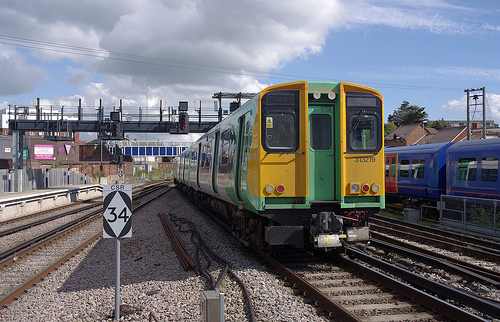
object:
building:
[108, 140, 193, 156]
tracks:
[0, 177, 500, 322]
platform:
[156, 174, 221, 276]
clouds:
[0, 1, 500, 123]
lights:
[349, 183, 381, 194]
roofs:
[384, 124, 482, 146]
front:
[259, 81, 384, 210]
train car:
[171, 81, 386, 215]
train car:
[385, 137, 500, 206]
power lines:
[0, 35, 463, 92]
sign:
[102, 184, 133, 238]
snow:
[247, 73, 394, 257]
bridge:
[8, 91, 245, 139]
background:
[0, 0, 499, 321]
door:
[306, 100, 342, 201]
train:
[384, 137, 500, 222]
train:
[172, 80, 386, 257]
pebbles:
[0, 190, 333, 322]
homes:
[383, 120, 500, 146]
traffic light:
[179, 113, 189, 133]